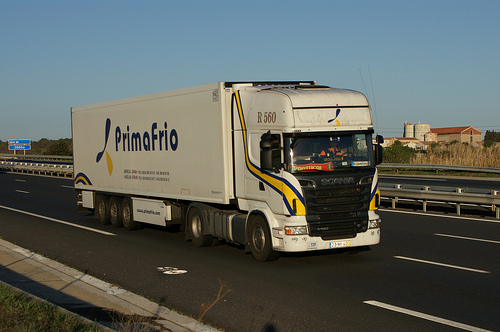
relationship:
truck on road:
[62, 77, 391, 263] [2, 170, 500, 330]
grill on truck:
[299, 176, 374, 238] [62, 77, 391, 263]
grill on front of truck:
[299, 176, 374, 238] [62, 77, 391, 263]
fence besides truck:
[1, 152, 498, 217] [62, 77, 391, 263]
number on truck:
[254, 110, 283, 122] [62, 77, 391, 263]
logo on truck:
[88, 115, 197, 182] [62, 77, 391, 263]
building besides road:
[367, 111, 488, 156] [2, 170, 500, 330]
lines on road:
[345, 212, 499, 331] [2, 170, 500, 330]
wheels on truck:
[77, 184, 289, 266] [62, 77, 391, 263]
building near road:
[367, 111, 488, 156] [2, 170, 500, 330]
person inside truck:
[311, 141, 353, 158] [62, 77, 391, 263]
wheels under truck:
[77, 184, 289, 266] [62, 77, 391, 263]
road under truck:
[2, 170, 500, 330] [62, 77, 391, 263]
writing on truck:
[112, 118, 186, 160] [62, 77, 391, 263]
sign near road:
[5, 136, 37, 153] [2, 170, 500, 330]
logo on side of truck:
[88, 115, 197, 182] [62, 77, 391, 263]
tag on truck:
[281, 160, 334, 174] [62, 77, 391, 263]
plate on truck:
[320, 238, 358, 251] [62, 77, 391, 263]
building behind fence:
[367, 111, 488, 156] [1, 152, 498, 217]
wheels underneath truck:
[77, 184, 289, 266] [62, 77, 391, 263]